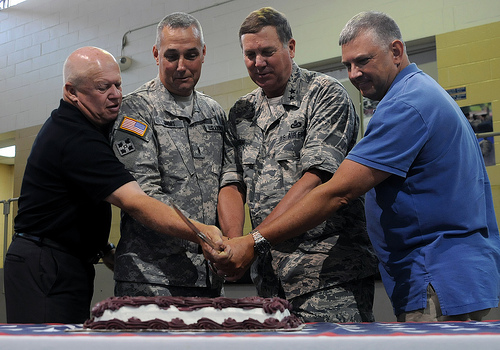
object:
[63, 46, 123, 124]
head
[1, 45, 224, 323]
body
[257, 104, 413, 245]
arm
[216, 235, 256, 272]
hand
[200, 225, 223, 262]
hand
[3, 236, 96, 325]
pants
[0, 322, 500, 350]
table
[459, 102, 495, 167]
pictures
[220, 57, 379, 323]
fatigues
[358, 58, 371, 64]
eye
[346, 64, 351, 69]
eye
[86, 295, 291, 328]
icing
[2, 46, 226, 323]
man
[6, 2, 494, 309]
wall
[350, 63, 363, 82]
nose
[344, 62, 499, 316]
shirt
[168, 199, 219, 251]
metal point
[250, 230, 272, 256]
silver watch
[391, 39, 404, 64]
ear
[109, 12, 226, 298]
man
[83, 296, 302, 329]
cake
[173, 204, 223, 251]
knife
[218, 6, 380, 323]
man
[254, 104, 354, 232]
arm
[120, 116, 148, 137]
flag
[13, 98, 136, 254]
shirt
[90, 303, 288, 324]
frosting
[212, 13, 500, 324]
man